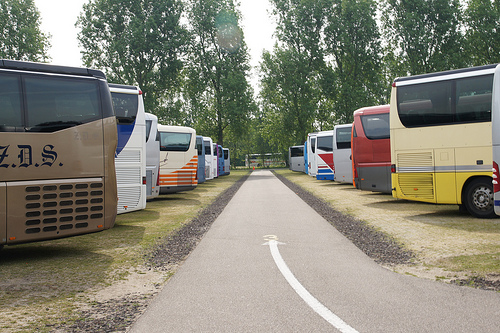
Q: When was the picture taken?
A: Daytime.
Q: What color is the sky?
A: White.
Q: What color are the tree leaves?
A: Green.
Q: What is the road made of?
A: Asphalt.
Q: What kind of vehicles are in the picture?
A: Buses.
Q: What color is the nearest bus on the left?
A: Gold.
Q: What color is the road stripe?
A: White.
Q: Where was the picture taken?
A: At a parking lot for buses.